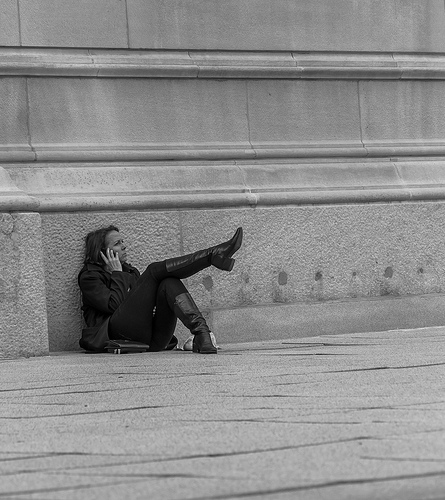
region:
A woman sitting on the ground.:
[0, 225, 443, 498]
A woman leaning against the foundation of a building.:
[0, 196, 442, 350]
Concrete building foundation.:
[0, 199, 444, 356]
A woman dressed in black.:
[78, 223, 242, 352]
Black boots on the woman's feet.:
[162, 223, 243, 352]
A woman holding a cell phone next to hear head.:
[83, 225, 127, 274]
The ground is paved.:
[0, 325, 442, 497]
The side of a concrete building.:
[0, 0, 442, 353]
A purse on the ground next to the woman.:
[178, 331, 216, 347]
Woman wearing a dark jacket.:
[75, 264, 139, 356]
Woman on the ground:
[70, 219, 256, 358]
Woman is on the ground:
[69, 220, 253, 357]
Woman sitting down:
[73, 221, 249, 357]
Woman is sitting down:
[68, 218, 254, 358]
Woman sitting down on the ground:
[68, 219, 258, 358]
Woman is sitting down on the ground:
[69, 216, 252, 360]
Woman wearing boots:
[160, 225, 254, 357]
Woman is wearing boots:
[159, 226, 260, 359]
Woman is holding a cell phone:
[99, 245, 124, 263]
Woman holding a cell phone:
[95, 235, 127, 262]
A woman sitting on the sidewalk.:
[59, 213, 304, 378]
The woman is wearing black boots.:
[159, 237, 248, 267]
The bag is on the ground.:
[104, 323, 153, 358]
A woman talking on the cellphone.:
[100, 243, 115, 265]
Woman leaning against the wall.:
[55, 213, 219, 351]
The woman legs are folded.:
[138, 242, 200, 341]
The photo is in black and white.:
[27, 45, 413, 421]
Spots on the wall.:
[248, 251, 422, 292]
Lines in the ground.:
[271, 343, 410, 442]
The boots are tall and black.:
[155, 209, 255, 277]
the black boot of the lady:
[173, 292, 213, 354]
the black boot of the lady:
[164, 225, 246, 277]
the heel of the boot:
[216, 255, 235, 270]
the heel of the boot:
[191, 339, 197, 351]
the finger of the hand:
[99, 248, 109, 261]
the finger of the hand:
[105, 245, 111, 259]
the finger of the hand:
[109, 248, 113, 256]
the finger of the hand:
[114, 250, 119, 255]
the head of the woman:
[84, 227, 126, 266]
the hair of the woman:
[82, 225, 119, 260]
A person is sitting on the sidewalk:
[21, 166, 391, 488]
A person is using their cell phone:
[36, 190, 373, 476]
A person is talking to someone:
[28, 168, 413, 496]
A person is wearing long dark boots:
[33, 179, 379, 476]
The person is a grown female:
[21, 194, 385, 473]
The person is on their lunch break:
[25, 185, 350, 454]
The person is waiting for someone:
[34, 192, 377, 459]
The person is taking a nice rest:
[30, 159, 417, 478]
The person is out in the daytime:
[46, 148, 381, 479]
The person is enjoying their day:
[44, 172, 380, 470]